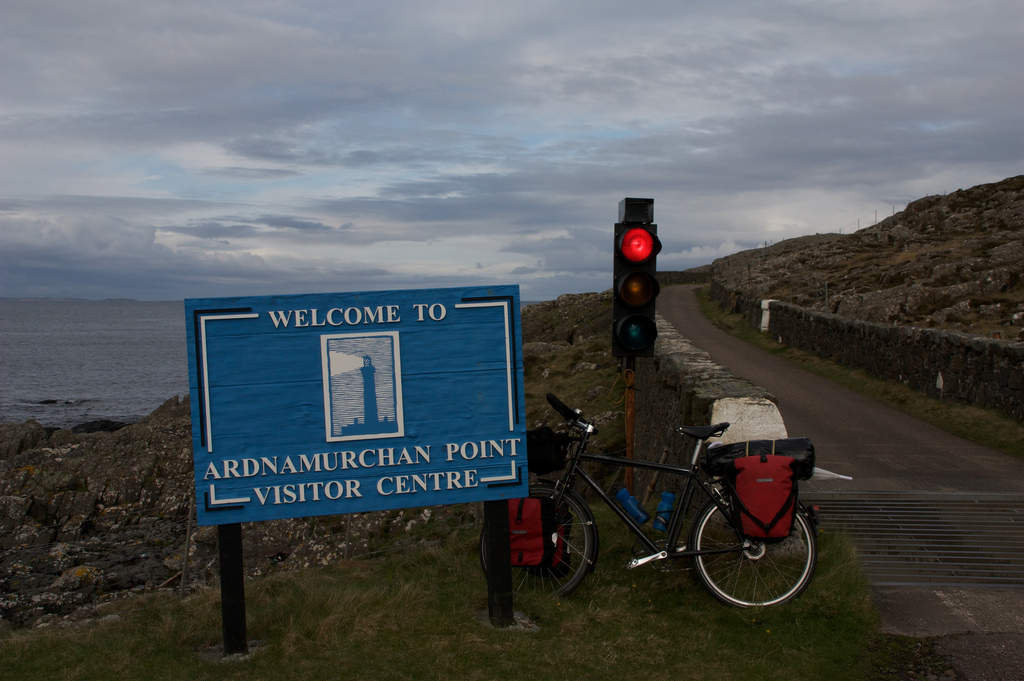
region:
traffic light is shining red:
[608, 188, 666, 376]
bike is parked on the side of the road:
[495, 389, 825, 618]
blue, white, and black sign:
[182, 284, 533, 532]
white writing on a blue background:
[264, 295, 457, 335]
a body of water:
[4, 288, 192, 425]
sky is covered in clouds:
[7, 3, 1019, 314]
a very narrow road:
[655, 269, 1023, 669]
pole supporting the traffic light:
[614, 367, 662, 501]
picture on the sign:
[317, 333, 419, 457]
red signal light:
[611, 198, 651, 271]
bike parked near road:
[517, 329, 827, 627]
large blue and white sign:
[155, 244, 558, 557]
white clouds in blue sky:
[198, 63, 317, 147]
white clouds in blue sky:
[415, 45, 488, 147]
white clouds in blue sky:
[29, 139, 134, 229]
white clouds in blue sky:
[134, 60, 210, 100]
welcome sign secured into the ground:
[178, 285, 534, 662]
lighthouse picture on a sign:
[318, 326, 408, 443]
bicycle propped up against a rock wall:
[475, 389, 820, 617]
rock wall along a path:
[706, 231, 1017, 425]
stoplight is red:
[606, 191, 665, 553]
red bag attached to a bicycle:
[729, 452, 800, 545]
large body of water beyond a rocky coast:
[4, 292, 192, 432]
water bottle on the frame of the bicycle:
[606, 478, 649, 529]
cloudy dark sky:
[5, 1, 1015, 299]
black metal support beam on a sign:
[479, 494, 519, 632]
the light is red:
[618, 224, 663, 264]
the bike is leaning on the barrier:
[673, 399, 820, 565]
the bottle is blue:
[606, 472, 657, 536]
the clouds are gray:
[525, 173, 596, 225]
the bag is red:
[742, 455, 781, 526]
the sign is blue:
[212, 281, 488, 491]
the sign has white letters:
[247, 446, 483, 498]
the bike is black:
[566, 427, 721, 582]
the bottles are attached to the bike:
[596, 443, 695, 584]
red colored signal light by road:
[593, 188, 666, 341]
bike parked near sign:
[536, 357, 832, 615]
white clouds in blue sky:
[316, 99, 390, 147]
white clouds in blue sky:
[777, 85, 877, 165]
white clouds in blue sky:
[88, 173, 180, 225]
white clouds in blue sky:
[258, 52, 342, 122]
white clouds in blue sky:
[359, 140, 420, 197]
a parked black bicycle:
[514, 386, 819, 611]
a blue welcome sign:
[174, 281, 530, 531]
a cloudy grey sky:
[18, 0, 1018, 297]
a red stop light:
[616, 227, 656, 262]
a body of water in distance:
[0, 300, 194, 424]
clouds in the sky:
[13, 28, 991, 231]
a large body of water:
[18, 291, 190, 440]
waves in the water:
[28, 298, 115, 368]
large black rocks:
[0, 401, 211, 582]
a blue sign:
[187, 300, 529, 649]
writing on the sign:
[218, 445, 507, 474]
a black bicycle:
[503, 394, 808, 597]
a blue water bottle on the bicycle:
[613, 489, 646, 522]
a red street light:
[610, 209, 669, 358]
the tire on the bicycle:
[692, 496, 807, 594]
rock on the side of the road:
[811, 257, 853, 300]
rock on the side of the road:
[931, 284, 950, 323]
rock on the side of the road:
[541, 332, 560, 356]